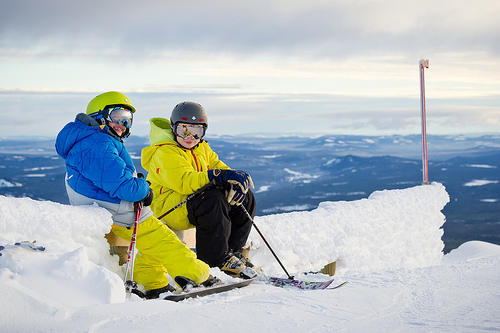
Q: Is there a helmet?
A: Yes, there is a helmet.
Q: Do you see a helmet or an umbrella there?
A: Yes, there is a helmet.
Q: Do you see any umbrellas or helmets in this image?
A: Yes, there is a helmet.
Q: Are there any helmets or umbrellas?
A: Yes, there is a helmet.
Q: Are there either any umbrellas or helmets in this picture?
A: Yes, there is a helmet.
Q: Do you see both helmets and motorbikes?
A: No, there is a helmet but no motorcycles.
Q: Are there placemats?
A: No, there are no placemats.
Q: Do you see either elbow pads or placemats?
A: No, there are no placemats or elbow pads.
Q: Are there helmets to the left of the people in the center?
A: Yes, there is a helmet to the left of the people.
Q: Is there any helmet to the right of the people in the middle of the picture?
A: No, the helmet is to the left of the people.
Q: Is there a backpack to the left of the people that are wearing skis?
A: No, there is a helmet to the left of the people.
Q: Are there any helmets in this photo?
A: Yes, there is a helmet.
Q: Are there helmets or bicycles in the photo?
A: Yes, there is a helmet.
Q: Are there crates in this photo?
A: No, there are no crates.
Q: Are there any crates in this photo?
A: No, there are no crates.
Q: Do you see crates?
A: No, there are no crates.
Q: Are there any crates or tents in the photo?
A: No, there are no crates or tents.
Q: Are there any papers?
A: No, there are no papers.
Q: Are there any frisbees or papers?
A: No, there are no papers or frisbees.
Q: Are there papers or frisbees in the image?
A: No, there are no papers or frisbees.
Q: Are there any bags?
A: No, there are no bags.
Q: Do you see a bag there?
A: No, there are no bags.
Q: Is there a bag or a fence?
A: No, there are no bags or fences.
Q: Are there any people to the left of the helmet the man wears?
A: No, the people are to the right of the helmet.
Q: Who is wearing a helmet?
A: The people are wearing a helmet.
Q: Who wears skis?
A: The people wear skis.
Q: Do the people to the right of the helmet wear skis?
A: Yes, the people wear skis.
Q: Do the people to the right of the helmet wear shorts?
A: No, the people wear skis.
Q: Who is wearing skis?
A: The people are wearing skis.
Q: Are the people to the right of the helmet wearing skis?
A: Yes, the people are wearing skis.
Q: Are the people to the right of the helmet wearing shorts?
A: No, the people are wearing skis.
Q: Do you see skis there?
A: Yes, there are skis.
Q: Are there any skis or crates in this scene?
A: Yes, there are skis.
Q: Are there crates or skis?
A: Yes, there are skis.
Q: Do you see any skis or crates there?
A: Yes, there are skis.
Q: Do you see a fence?
A: No, there are no fences.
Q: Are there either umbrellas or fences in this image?
A: No, there are no fences or umbrellas.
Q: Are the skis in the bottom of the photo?
A: Yes, the skis are in the bottom of the image.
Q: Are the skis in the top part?
A: No, the skis are in the bottom of the image.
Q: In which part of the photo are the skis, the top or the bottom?
A: The skis are in the bottom of the image.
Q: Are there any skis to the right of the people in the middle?
A: Yes, there are skis to the right of the people.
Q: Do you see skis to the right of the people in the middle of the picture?
A: Yes, there are skis to the right of the people.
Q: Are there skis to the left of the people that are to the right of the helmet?
A: No, the skis are to the right of the people.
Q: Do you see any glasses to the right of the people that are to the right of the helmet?
A: No, there are skis to the right of the people.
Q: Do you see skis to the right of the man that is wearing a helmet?
A: Yes, there are skis to the right of the man.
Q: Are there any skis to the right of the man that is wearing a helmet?
A: Yes, there are skis to the right of the man.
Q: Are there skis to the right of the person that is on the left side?
A: Yes, there are skis to the right of the man.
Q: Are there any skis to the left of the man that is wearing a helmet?
A: No, the skis are to the right of the man.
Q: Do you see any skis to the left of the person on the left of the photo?
A: No, the skis are to the right of the man.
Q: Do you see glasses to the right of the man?
A: No, there are skis to the right of the man.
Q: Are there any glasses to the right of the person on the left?
A: No, there are skis to the right of the man.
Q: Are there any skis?
A: Yes, there are skis.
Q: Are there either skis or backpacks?
A: Yes, there are skis.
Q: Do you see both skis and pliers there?
A: No, there are skis but no pliers.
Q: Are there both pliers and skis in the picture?
A: No, there are skis but no pliers.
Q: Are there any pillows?
A: No, there are no pillows.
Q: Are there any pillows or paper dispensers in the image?
A: No, there are no pillows or paper dispensers.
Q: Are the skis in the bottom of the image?
A: Yes, the skis are in the bottom of the image.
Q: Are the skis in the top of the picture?
A: No, the skis are in the bottom of the image.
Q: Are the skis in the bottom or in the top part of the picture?
A: The skis are in the bottom of the image.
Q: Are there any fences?
A: No, there are no fences.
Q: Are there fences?
A: No, there are no fences.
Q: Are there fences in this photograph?
A: No, there are no fences.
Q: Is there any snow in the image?
A: Yes, there is snow.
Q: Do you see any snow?
A: Yes, there is snow.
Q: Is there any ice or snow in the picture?
A: Yes, there is snow.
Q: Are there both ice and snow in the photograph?
A: No, there is snow but no ice.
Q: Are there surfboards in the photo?
A: No, there are no surfboards.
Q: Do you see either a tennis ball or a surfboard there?
A: No, there are no surfboards or tennis balls.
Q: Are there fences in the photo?
A: No, there are no fences.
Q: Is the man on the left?
A: Yes, the man is on the left of the image.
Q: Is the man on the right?
A: No, the man is on the left of the image.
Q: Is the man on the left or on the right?
A: The man is on the left of the image.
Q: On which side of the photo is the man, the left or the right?
A: The man is on the left of the image.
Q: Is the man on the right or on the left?
A: The man is on the left of the image.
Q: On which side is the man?
A: The man is on the left of the image.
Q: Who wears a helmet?
A: The man wears a helmet.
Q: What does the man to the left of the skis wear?
A: The man wears a helmet.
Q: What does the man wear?
A: The man wears a helmet.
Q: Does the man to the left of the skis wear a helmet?
A: Yes, the man wears a helmet.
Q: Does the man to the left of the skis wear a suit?
A: No, the man wears a helmet.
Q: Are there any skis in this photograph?
A: Yes, there are skis.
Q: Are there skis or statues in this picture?
A: Yes, there are skis.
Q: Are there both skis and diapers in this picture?
A: No, there are skis but no diapers.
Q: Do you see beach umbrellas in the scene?
A: No, there are no beach umbrellas.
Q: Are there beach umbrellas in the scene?
A: No, there are no beach umbrellas.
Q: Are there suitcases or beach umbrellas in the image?
A: No, there are no beach umbrellas or suitcases.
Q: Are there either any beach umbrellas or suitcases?
A: No, there are no beach umbrellas or suitcases.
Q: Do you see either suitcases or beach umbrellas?
A: No, there are no beach umbrellas or suitcases.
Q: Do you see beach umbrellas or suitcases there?
A: No, there are no beach umbrellas or suitcases.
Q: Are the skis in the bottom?
A: Yes, the skis are in the bottom of the image.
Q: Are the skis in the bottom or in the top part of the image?
A: The skis are in the bottom of the image.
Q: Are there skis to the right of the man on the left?
A: Yes, there are skis to the right of the man.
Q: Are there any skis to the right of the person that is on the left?
A: Yes, there are skis to the right of the man.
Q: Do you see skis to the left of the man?
A: No, the skis are to the right of the man.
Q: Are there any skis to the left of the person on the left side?
A: No, the skis are to the right of the man.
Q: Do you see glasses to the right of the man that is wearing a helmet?
A: No, there are skis to the right of the man.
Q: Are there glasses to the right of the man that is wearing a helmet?
A: No, there are skis to the right of the man.